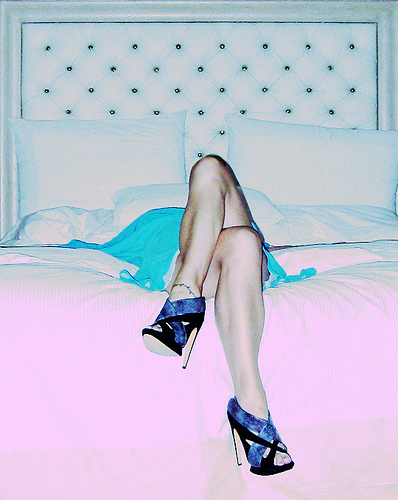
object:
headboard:
[0, 0, 397, 244]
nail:
[45, 45, 51, 50]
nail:
[88, 44, 93, 52]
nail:
[131, 43, 137, 51]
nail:
[175, 42, 182, 50]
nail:
[218, 43, 226, 51]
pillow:
[10, 115, 189, 231]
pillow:
[227, 114, 397, 221]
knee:
[190, 145, 235, 187]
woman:
[56, 155, 317, 476]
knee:
[227, 220, 265, 259]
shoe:
[140, 293, 206, 370]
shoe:
[227, 395, 295, 476]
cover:
[0, 245, 395, 500]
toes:
[283, 455, 293, 467]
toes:
[146, 324, 158, 332]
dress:
[61, 206, 316, 289]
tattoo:
[168, 282, 196, 300]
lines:
[21, 18, 378, 28]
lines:
[2, 233, 397, 255]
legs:
[172, 225, 269, 433]